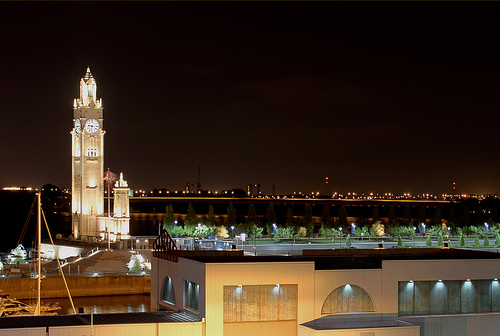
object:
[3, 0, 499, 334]
photograph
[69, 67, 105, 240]
clock tower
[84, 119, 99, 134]
clocks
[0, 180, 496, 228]
city lights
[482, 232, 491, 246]
trees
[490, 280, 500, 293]
lights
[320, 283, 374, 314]
window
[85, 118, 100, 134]
clock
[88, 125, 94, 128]
black hands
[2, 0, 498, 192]
sky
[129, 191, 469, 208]
lights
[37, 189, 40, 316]
pole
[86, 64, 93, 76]
spire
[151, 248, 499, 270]
roof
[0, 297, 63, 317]
boat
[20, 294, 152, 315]
water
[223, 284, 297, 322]
windows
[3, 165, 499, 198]
skyline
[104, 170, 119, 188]
flag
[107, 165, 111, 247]
pole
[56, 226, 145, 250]
building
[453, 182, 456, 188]
lights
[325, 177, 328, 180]
lights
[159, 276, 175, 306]
window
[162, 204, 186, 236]
tree